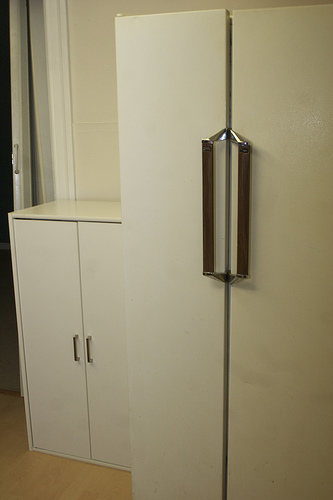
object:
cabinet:
[5, 196, 139, 477]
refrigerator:
[113, 0, 330, 499]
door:
[74, 216, 133, 473]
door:
[10, 211, 93, 466]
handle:
[228, 125, 254, 287]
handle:
[199, 125, 231, 285]